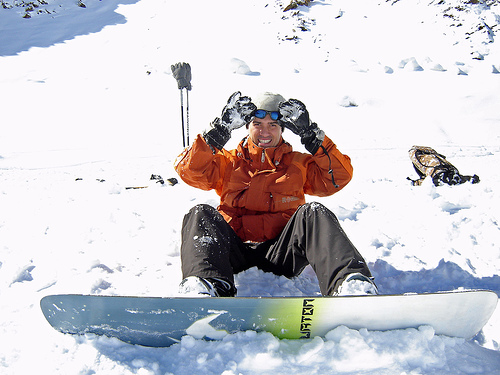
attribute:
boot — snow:
[189, 255, 396, 299]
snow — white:
[61, 102, 128, 167]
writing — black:
[292, 300, 321, 334]